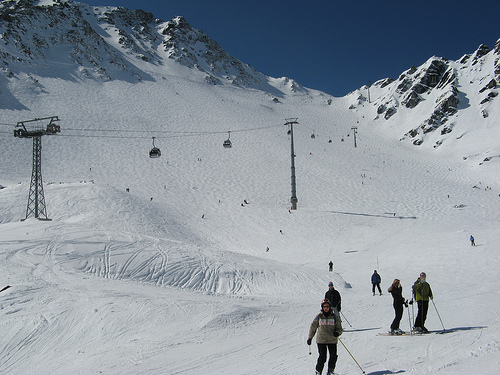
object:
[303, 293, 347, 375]
person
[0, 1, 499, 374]
snow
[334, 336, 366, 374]
ski pole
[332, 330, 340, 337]
hand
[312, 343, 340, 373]
pants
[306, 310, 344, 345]
jacket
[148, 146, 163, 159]
ski lift chair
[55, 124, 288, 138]
wire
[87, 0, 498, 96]
sky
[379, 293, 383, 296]
ski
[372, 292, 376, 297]
ski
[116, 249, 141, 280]
ski tracks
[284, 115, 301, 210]
pole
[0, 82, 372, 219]
ski lift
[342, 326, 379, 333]
shadow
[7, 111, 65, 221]
tower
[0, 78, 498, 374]
ski slope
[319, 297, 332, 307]
helmet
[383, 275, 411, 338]
skier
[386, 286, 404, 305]
jacket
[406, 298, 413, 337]
ski pole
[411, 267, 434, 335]
skier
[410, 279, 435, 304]
jacket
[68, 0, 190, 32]
top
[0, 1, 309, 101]
mountain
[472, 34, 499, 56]
top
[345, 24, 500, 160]
mountain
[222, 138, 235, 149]
ski lift chair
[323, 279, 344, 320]
skier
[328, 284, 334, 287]
goggles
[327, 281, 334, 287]
hat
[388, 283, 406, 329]
black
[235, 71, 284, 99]
shadow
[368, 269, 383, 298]
skier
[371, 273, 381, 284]
jacket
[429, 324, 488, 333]
shadow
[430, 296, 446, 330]
ski pole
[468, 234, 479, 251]
skier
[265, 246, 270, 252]
skier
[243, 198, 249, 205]
skier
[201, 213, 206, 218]
skier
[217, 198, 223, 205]
skier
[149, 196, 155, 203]
skier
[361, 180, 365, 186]
skier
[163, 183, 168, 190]
skier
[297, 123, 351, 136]
wire